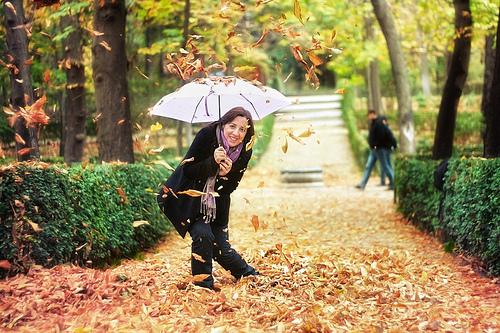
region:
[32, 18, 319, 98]
the leaves are falling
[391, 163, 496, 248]
the bushes are green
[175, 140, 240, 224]
the coat is black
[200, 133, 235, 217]
the scarf is purple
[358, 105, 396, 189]
the people are walking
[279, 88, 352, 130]
the steps are concrete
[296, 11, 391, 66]
the leaves are green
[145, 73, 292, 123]
White umbrella over woman's head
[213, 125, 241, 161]
Purple scarf on woman's neck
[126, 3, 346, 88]
Leaves falling over umbrella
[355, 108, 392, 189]
Man walking across a sidewalk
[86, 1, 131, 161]
Brown trunk of tree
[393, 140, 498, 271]
Green hedge around the path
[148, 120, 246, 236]
Black coat on woman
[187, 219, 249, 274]
Black pants on woman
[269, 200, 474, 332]
Pile of leaves on a path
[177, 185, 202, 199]
Orange leaf in front of woman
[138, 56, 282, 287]
a woman holding an umbrella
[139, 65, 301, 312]
a woman wearing ablack buisness jacket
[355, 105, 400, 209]
a man walking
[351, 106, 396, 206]
a man wearing a hat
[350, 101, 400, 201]
a man wearing jeans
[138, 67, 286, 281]
a woman wearing a purple scarf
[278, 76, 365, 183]
a wooden walking bridge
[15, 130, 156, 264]
green hedge bushes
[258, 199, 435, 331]
leaves that have fallen to the ground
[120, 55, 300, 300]
a woman with her legs crossed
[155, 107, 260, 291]
woman posing for the photo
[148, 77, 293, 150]
white umbrella with a black handle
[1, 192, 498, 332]
pile of brown dead leaves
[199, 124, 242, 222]
light purple silk scarf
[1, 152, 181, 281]
trimmed row of hedges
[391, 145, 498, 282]
trimmed row of hedges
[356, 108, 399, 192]
people walking in the background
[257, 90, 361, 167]
concrete stairs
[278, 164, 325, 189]
poured concrete fountain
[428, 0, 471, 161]
dark trunk of a tree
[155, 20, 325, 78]
gold leaves blowing in the air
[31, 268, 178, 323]
many leaves on the ground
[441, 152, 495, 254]
well manicured hedges on the side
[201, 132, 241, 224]
purple scarf around woman's neck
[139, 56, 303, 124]
white umbrella with spine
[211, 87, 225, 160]
handle of white umbrella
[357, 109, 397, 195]
people walking on the path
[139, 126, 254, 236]
woman wearing black coat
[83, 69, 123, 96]
small stump in tree trunk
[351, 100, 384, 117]
brown cap on man's head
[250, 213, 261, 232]
brown leaf falling to ground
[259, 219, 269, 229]
brown leaf falling to ground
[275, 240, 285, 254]
brown leaf falling to ground